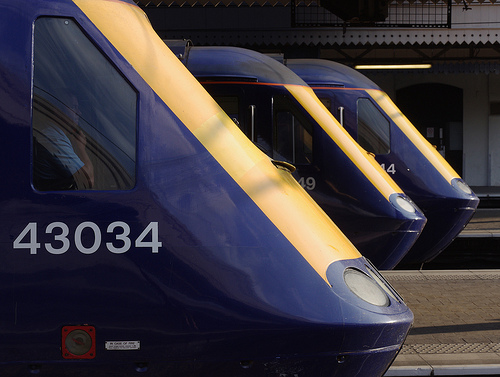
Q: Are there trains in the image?
A: Yes, there is a train.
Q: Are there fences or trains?
A: Yes, there is a train.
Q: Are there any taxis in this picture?
A: No, there are no taxis.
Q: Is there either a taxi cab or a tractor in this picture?
A: No, there are no taxis or tractors.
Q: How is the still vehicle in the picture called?
A: The vehicle is a train.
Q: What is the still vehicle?
A: The vehicle is a train.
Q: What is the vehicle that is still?
A: The vehicle is a train.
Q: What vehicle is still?
A: The vehicle is a train.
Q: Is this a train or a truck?
A: This is a train.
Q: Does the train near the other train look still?
A: Yes, the train is still.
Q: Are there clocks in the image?
A: No, there are no clocks.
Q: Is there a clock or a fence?
A: No, there are no clocks or fences.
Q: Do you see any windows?
A: Yes, there is a window.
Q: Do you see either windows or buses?
A: Yes, there is a window.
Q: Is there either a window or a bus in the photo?
A: Yes, there is a window.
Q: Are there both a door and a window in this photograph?
A: No, there is a window but no doors.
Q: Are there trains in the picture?
A: Yes, there is a train.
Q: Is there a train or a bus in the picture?
A: Yes, there is a train.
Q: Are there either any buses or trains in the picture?
A: Yes, there is a train.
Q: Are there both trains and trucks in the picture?
A: No, there is a train but no trucks.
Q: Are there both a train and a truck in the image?
A: No, there is a train but no trucks.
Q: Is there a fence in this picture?
A: No, there are no fences.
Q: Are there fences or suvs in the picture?
A: No, there are no fences or suvs.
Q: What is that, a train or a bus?
A: That is a train.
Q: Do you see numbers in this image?
A: Yes, there are numbers.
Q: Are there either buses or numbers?
A: Yes, there are numbers.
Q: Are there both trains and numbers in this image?
A: Yes, there are both numbers and a train.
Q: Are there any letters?
A: No, there are no letters.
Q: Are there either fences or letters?
A: No, there are no letters or fences.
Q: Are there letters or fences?
A: No, there are no letters or fences.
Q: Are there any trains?
A: Yes, there is a train.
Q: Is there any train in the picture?
A: Yes, there is a train.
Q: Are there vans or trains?
A: Yes, there is a train.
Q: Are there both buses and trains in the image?
A: No, there is a train but no buses.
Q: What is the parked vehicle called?
A: The vehicle is a train.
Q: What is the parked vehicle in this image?
A: The vehicle is a train.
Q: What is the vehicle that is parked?
A: The vehicle is a train.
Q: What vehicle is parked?
A: The vehicle is a train.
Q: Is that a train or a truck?
A: That is a train.